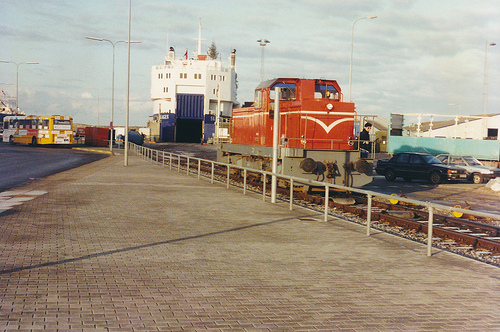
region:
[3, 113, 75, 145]
Yellow and white bus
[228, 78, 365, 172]
Red train engine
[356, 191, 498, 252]
Rusty looking Railroad track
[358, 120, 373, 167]
Guy in all black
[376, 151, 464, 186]
four door car in the shade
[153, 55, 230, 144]
A large white building structure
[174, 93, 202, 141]
garage type door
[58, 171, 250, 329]
neatly bricked sidewalk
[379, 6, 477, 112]
alot of cloud coverage in the sky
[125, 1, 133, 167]
very tall metal pole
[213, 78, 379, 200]
Red train engine on train track.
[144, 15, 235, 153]
Large white building in background.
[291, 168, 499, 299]
Metal rail along edge of road next to train track.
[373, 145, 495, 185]
Cars parked in parking lot.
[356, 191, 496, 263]
One set of railroad tracks.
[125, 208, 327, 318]
Red brick paved sidewalk.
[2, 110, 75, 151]
Yellow bus parked on side of street.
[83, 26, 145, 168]
Light post standing on sidewalk.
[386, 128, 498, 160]
Blue fence surrounding building.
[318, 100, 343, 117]
Headlight on front of train.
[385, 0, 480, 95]
clouds in the sky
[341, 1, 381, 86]
tall street light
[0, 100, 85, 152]
bus parked on the street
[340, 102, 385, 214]
man working at train yard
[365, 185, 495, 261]
short stretch of single track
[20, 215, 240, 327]
neat pavement of brick work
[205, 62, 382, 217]
train engine making its way along the track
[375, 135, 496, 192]
cars parked in the train yard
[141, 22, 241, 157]
white building with front entrance open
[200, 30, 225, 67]
tree growing on top of building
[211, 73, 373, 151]
a orange train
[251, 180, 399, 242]
a steel fence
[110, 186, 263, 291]
a brick road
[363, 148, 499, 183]
two cars beside train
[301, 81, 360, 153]
the front of train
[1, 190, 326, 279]
a shadow of a pole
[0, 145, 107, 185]
blacktop meets brick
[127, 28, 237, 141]
a round white building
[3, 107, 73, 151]
a yellow and white bus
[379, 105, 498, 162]
a light blue trailer behind cars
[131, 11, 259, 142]
a tall building.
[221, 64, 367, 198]
a red train engine.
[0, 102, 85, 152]
a yellow and white bus.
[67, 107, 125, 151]
a parked vehicle.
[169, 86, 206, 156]
a large blue hangar door.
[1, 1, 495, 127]
a gray cloudy sky.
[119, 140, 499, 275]
a metal railing.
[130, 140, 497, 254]
a set of rusted train tracks.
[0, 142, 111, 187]
a curvy paved road.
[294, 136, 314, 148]
a headlight on a red train engine.